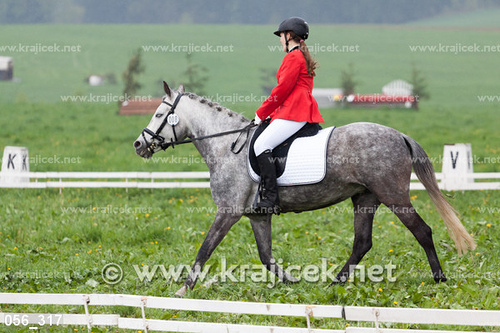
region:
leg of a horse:
[188, 220, 226, 281]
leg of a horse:
[250, 227, 296, 273]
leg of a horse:
[341, 221, 378, 264]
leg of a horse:
[393, 229, 454, 264]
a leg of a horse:
[178, 221, 242, 293]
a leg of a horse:
[241, 227, 293, 267]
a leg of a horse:
[386, 208, 461, 269]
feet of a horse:
[171, 267, 202, 299]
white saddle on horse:
[297, 145, 310, 168]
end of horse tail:
[456, 228, 475, 258]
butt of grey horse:
[370, 137, 411, 181]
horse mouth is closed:
[131, 137, 157, 159]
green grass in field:
[79, 199, 109, 236]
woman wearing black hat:
[287, 19, 300, 26]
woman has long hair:
[303, 50, 318, 77]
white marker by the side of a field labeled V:
[438, 142, 474, 191]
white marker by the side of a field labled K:
[1, 144, 29, 183]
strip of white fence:
[115, 290, 340, 330]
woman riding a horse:
[131, 15, 473, 295]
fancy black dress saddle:
[247, 115, 317, 175]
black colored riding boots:
[250, 146, 275, 211]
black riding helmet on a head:
[271, 15, 306, 46]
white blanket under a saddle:
[245, 125, 330, 180]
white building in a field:
[380, 76, 411, 106]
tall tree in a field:
[406, 62, 428, 104]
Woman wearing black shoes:
[245, 147, 282, 220]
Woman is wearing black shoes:
[237, 148, 287, 222]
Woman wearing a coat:
[253, 47, 325, 125]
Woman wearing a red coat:
[259, 46, 325, 127]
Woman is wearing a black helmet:
[273, 12, 319, 39]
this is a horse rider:
[10, 21, 457, 295]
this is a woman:
[252, 5, 331, 129]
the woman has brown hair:
[292, 45, 341, 85]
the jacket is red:
[273, 33, 343, 129]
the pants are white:
[252, 110, 311, 166]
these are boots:
[255, 158, 297, 220]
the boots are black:
[250, 150, 339, 270]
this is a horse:
[165, 85, 412, 220]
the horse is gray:
[144, 96, 391, 226]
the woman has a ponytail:
[282, 15, 339, 98]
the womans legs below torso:
[249, 115, 307, 215]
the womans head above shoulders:
[278, 19, 311, 52]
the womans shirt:
[267, 50, 331, 121]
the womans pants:
[258, 110, 305, 152]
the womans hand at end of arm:
[252, 111, 264, 125]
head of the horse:
[132, 82, 194, 162]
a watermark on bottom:
[72, 222, 419, 324]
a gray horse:
[110, 75, 485, 290]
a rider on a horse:
[195, 5, 355, 226]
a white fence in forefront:
[5, 265, 455, 330]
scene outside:
[16, 16, 472, 331]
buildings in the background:
[53, 55, 495, 165]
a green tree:
[102, 38, 157, 113]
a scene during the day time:
[14, 13, 474, 329]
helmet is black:
[272, 17, 309, 41]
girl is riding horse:
[241, 17, 323, 214]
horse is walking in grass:
[131, 79, 481, 295]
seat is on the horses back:
[248, 116, 338, 185]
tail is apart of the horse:
[402, 134, 474, 255]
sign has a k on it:
[2, 143, 28, 182]